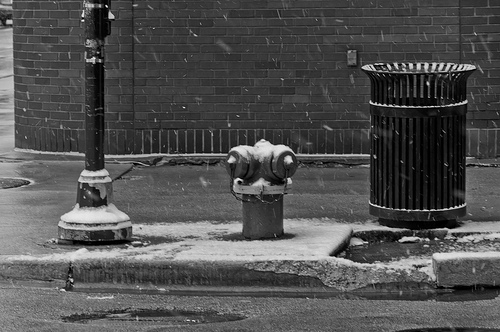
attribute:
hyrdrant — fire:
[218, 133, 303, 243]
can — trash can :
[190, 49, 499, 250]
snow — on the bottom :
[52, 197, 134, 229]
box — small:
[343, 47, 360, 67]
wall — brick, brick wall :
[8, 2, 498, 158]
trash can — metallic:
[354, 52, 481, 230]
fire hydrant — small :
[220, 133, 310, 256]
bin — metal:
[350, 40, 482, 237]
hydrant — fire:
[252, 200, 276, 232]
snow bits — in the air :
[109, 18, 354, 181]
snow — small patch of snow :
[45, 213, 499, 270]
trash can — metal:
[362, 62, 476, 222]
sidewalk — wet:
[28, 121, 480, 307]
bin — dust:
[359, 58, 477, 229]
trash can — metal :
[342, 50, 484, 232]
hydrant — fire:
[221, 134, 304, 240]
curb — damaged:
[242, 256, 432, 291]